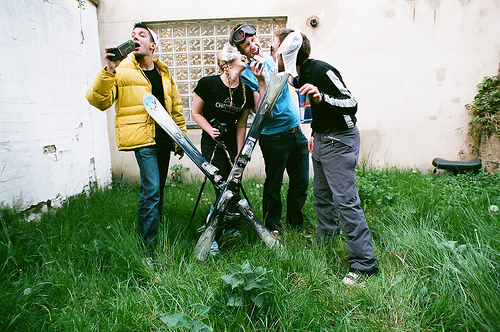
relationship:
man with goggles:
[271, 72, 310, 134] [228, 25, 300, 39]